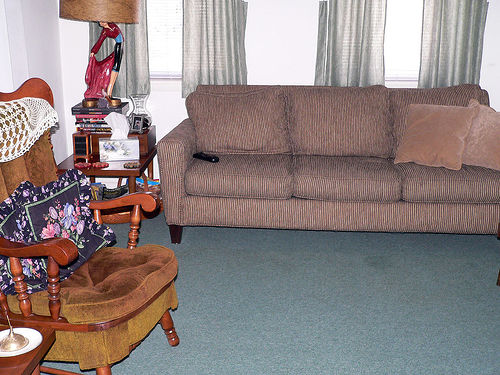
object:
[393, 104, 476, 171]
pillows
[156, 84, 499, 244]
sofa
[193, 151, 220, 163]
remote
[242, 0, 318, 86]
windows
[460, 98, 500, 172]
pillows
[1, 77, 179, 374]
chair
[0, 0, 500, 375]
living room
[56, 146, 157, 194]
end table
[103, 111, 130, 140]
facial tissue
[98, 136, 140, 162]
box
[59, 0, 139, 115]
lamp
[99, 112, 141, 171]
tissues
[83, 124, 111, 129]
books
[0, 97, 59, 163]
doily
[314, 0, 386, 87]
curtains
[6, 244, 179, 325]
cushion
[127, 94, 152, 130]
vase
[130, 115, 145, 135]
picture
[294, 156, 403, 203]
cushion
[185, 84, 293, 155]
back cushion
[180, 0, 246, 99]
drapes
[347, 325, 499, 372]
carpet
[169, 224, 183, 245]
leg